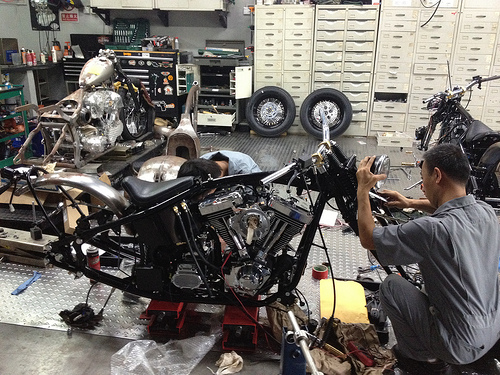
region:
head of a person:
[403, 130, 470, 202]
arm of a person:
[345, 140, 386, 241]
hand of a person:
[360, 151, 386, 178]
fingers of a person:
[351, 153, 381, 163]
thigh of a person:
[390, 275, 453, 340]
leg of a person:
[382, 310, 433, 352]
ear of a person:
[431, 167, 444, 183]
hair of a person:
[437, 141, 468, 166]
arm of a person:
[396, 191, 441, 212]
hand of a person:
[382, 179, 405, 205]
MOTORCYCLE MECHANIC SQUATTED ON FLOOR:
[346, 136, 497, 366]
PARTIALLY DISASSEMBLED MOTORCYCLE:
[14, 134, 373, 337]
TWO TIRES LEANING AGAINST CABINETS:
[240, 80, 357, 141]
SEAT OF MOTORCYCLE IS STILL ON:
[107, 163, 209, 216]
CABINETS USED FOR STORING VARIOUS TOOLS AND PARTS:
[245, 3, 497, 110]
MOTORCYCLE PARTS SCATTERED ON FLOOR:
[28, 322, 385, 369]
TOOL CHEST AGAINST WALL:
[179, 33, 257, 135]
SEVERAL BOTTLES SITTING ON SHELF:
[5, 30, 66, 72]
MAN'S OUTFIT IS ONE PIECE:
[346, 163, 498, 368]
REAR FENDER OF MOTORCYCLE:
[1, 167, 139, 209]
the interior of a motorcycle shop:
[0, 0, 499, 374]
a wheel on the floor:
[298, 87, 352, 139]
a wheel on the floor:
[244, 85, 295, 137]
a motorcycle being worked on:
[0, 107, 422, 307]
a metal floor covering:
[0, 130, 498, 355]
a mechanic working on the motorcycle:
[355, 143, 499, 373]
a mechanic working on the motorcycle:
[176, 150, 261, 252]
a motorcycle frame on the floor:
[136, 80, 199, 182]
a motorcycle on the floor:
[403, 74, 498, 215]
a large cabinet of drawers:
[253, 5, 315, 135]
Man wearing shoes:
[382, 335, 498, 372]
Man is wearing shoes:
[387, 344, 499, 373]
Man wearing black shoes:
[387, 342, 498, 371]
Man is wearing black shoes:
[387, 340, 498, 373]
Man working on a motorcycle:
[8, 112, 498, 372]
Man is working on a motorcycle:
[9, 107, 499, 374]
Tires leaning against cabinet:
[242, 81, 354, 138]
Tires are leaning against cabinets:
[240, 82, 354, 139]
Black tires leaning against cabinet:
[241, 85, 352, 138]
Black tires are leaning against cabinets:
[244, 82, 354, 140]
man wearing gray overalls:
[354, 145, 499, 372]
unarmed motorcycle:
[28, 110, 402, 313]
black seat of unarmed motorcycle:
[123, 175, 190, 204]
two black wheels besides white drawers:
[248, 87, 353, 137]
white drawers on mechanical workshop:
[258, 3, 498, 141]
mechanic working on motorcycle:
[351, 145, 498, 372]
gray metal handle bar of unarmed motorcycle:
[197, 104, 331, 222]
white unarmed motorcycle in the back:
[13, 47, 149, 186]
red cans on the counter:
[16, 37, 42, 70]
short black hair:
[423, 143, 468, 187]